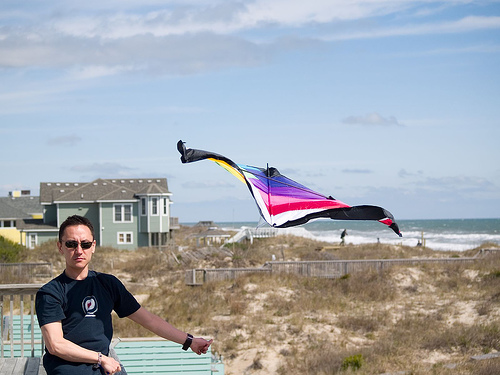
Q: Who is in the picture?
A: A man in black shirt.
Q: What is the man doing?
A: Flying a kite.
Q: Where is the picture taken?
A: On the beach.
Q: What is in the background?
A: Beach house.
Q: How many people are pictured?
A: 2.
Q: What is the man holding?
A: String to the kite.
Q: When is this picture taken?
A: Morning.